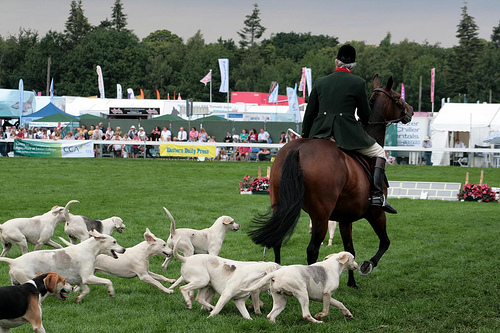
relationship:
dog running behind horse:
[239, 250, 358, 323] [251, 71, 419, 293]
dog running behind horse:
[159, 207, 240, 268] [251, 71, 419, 293]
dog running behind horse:
[6, 200, 71, 258] [251, 71, 419, 293]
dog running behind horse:
[97, 227, 176, 289] [251, 71, 419, 293]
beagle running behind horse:
[0, 271, 73, 333] [251, 71, 419, 293]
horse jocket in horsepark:
[3, 42, 418, 318] [1, 33, 497, 330]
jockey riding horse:
[296, 44, 413, 213] [227, 69, 445, 310]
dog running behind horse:
[239, 250, 358, 323] [277, 77, 414, 278]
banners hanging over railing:
[12, 137, 92, 158] [1, 140, 271, 160]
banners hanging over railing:
[159, 144, 214, 156] [1, 140, 271, 160]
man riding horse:
[298, 43, 396, 216] [251, 71, 419, 293]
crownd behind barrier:
[1, 126, 274, 161] [2, 137, 498, 167]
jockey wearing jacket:
[296, 41, 401, 216] [299, 69, 379, 154]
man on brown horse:
[302, 43, 398, 216] [260, 126, 400, 251]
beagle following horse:
[0, 271, 73, 333] [251, 66, 429, 282]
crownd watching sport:
[75, 116, 275, 147] [9, 108, 303, 168]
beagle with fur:
[0, 271, 73, 333] [114, 240, 152, 271]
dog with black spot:
[64, 199, 127, 244] [85, 216, 107, 230]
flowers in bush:
[457, 181, 493, 201] [458, 182, 498, 203]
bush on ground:
[458, 182, 498, 203] [1, 153, 499, 330]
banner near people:
[156, 142, 222, 159] [3, 118, 296, 160]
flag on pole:
[198, 67, 213, 84] [208, 64, 213, 106]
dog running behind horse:
[64, 194, 127, 246] [262, 70, 412, 283]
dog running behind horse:
[165, 205, 317, 305] [197, 49, 425, 269]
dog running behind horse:
[58, 227, 176, 295] [267, 136, 362, 242]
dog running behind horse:
[239, 250, 358, 323] [259, 133, 392, 231]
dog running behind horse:
[245, 237, 377, 319] [264, 139, 368, 223]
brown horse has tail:
[242, 73, 414, 286] [237, 142, 328, 282]